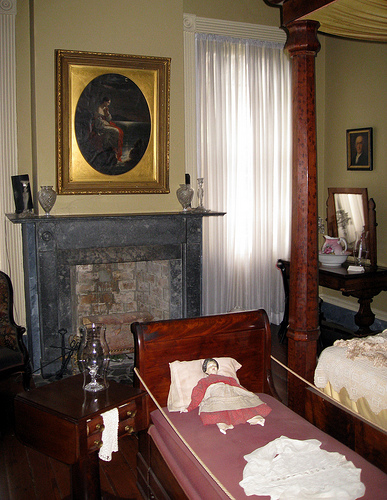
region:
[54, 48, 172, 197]
A painting on a wall.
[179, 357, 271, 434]
A doll in a bed.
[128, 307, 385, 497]
An old wood bed.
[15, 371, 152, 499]
An old wood table.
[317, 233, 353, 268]
A water picture and bowl.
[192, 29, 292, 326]
A curtain on a window.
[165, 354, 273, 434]
A doll on a pillow.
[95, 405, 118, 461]
A towel on a drawer.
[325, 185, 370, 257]
A wood framed mirror.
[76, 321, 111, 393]
A glass jar on a table.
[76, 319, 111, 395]
Empty glass vase on a table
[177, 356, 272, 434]
Doll wearing a red and white dress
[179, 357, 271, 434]
Creepy doll lying in a crib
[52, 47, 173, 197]
Circular painting with gold matting and frame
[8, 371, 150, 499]
Dark brown wood side table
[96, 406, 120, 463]
White cloth hanging from a drawer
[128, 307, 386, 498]
Dark brown wood crib with pink mattress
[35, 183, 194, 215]
Two crystal vases on a fireplace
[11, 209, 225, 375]
Gray stone fireplace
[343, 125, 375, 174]
Portrait of a man in a frame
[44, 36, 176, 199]
a painting on the wall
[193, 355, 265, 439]
a doll in a bed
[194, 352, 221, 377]
the head of a doll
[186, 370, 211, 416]
the right arm of a doll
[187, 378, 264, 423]
the dress of a doll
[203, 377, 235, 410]
the apron of a doll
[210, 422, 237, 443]
the right leg of a doll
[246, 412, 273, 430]
the left leg of a doll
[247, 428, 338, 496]
the white blanket of a doll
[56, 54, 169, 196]
iol painting in gold frame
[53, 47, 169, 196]
oil painting in gold mat above fireplace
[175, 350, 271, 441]
antique china doll with black hair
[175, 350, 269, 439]
doll wearing red gingham dress and white pinafore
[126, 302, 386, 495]
cherry sleigh bed for child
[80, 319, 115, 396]
glass globe over candlestick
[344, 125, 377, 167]
small guilt framed oil painting of formr president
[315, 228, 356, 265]
china flowered basin and pitcher for water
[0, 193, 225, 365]
grey stone Victorian fireplce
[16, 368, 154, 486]
cherry nightstand with 2 drawers with brass pulls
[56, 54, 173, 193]
a picture on the wall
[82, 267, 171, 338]
a fireplace on the wall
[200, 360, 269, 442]
a doll on the bed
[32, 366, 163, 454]
a wooden end table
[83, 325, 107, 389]
a vase on the end table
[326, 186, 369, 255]
a mirror on the dresser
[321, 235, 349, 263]
a pink vase on the dresser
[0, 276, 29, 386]
a chair next to the fireplace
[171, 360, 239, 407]
a pillow on the bed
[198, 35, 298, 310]
curtains on the window